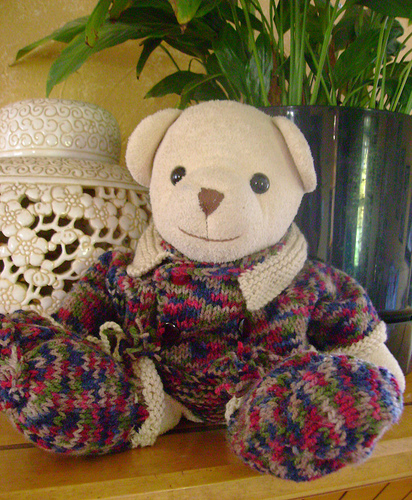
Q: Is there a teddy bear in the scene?
A: Yes, there is a teddy bear.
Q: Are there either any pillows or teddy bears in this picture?
A: Yes, there is a teddy bear.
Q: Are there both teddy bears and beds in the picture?
A: No, there is a teddy bear but no beds.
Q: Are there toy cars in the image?
A: No, there are no toy cars.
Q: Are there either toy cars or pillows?
A: No, there are no toy cars or pillows.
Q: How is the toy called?
A: The toy is a teddy bear.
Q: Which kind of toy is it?
A: The toy is a teddy bear.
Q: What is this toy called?
A: This is a teddy bear.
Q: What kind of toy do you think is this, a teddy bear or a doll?
A: This is a teddy bear.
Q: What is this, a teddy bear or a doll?
A: This is a teddy bear.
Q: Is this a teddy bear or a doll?
A: This is a teddy bear.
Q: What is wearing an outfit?
A: The teddy bear is wearing an outfit.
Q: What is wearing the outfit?
A: The teddy bear is wearing an outfit.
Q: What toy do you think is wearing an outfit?
A: The toy is a teddy bear.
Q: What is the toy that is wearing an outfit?
A: The toy is a teddy bear.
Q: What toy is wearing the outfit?
A: The toy is a teddy bear.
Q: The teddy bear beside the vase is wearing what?
A: The teddy bear is wearing an outfit.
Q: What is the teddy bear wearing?
A: The teddy bear is wearing an outfit.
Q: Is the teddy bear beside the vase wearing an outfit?
A: Yes, the teddy bear is wearing an outfit.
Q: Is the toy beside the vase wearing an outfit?
A: Yes, the teddy bear is wearing an outfit.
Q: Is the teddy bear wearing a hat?
A: No, the teddy bear is wearing an outfit.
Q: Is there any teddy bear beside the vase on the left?
A: Yes, there is a teddy bear beside the vase.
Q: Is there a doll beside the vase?
A: No, there is a teddy bear beside the vase.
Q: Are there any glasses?
A: No, there are no glasses.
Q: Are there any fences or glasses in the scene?
A: No, there are no glasses or fences.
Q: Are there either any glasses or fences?
A: No, there are no glasses or fences.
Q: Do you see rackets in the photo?
A: No, there are no rackets.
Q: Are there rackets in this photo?
A: No, there are no rackets.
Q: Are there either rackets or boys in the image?
A: No, there are no rackets or boys.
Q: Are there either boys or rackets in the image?
A: No, there are no rackets or boys.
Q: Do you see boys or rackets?
A: No, there are no rackets or boys.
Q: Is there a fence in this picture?
A: No, there are no fences.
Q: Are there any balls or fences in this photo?
A: No, there are no fences or balls.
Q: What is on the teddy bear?
A: The outfit is on the teddy bear.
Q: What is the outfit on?
A: The outfit is on the teddy bear.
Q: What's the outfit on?
A: The outfit is on the teddy bear.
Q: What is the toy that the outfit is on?
A: The toy is a teddy bear.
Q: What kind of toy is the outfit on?
A: The outfit is on the teddy bear.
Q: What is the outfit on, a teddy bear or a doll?
A: The outfit is on a teddy bear.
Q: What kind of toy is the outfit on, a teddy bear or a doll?
A: The outfit is on a teddy bear.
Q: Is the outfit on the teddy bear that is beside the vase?
A: Yes, the outfit is on the teddy bear.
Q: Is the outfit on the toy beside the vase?
A: Yes, the outfit is on the teddy bear.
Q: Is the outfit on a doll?
A: No, the outfit is on the teddy bear.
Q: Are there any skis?
A: No, there are no skis.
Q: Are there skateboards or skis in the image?
A: No, there are no skis or skateboards.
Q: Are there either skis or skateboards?
A: No, there are no skis or skateboards.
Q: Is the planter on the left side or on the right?
A: The planter is on the right of the image.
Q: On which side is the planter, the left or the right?
A: The planter is on the right of the image.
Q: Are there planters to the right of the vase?
A: Yes, there is a planter to the right of the vase.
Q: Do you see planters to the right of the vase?
A: Yes, there is a planter to the right of the vase.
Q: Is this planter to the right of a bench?
A: No, the planter is to the right of the vase.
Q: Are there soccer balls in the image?
A: No, there are no soccer balls.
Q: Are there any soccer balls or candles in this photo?
A: No, there are no soccer balls or candles.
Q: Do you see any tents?
A: No, there are no tents.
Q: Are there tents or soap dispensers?
A: No, there are no tents or soap dispensers.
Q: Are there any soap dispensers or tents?
A: No, there are no tents or soap dispensers.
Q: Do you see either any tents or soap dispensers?
A: No, there are no tents or soap dispensers.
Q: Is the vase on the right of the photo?
A: No, the vase is on the left of the image.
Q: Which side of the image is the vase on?
A: The vase is on the left of the image.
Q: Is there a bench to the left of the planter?
A: No, there is a vase to the left of the planter.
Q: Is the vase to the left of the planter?
A: Yes, the vase is to the left of the planter.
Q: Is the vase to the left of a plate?
A: No, the vase is to the left of the planter.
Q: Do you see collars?
A: Yes, there is a collar.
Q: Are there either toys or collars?
A: Yes, there is a collar.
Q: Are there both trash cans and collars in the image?
A: No, there is a collar but no trash cans.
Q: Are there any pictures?
A: No, there are no pictures.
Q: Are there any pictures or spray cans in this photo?
A: No, there are no pictures or spray cans.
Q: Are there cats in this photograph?
A: No, there are no cats.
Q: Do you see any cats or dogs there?
A: No, there are no cats or dogs.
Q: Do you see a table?
A: Yes, there is a table.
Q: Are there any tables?
A: Yes, there is a table.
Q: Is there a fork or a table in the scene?
A: Yes, there is a table.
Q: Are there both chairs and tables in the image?
A: No, there is a table but no chairs.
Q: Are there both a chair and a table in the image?
A: No, there is a table but no chairs.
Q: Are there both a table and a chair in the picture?
A: No, there is a table but no chairs.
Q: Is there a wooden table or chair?
A: Yes, there is a wood table.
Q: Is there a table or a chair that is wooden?
A: Yes, the table is wooden.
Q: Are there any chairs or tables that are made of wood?
A: Yes, the table is made of wood.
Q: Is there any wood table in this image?
A: Yes, there is a wood table.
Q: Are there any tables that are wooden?
A: Yes, there is a table that is wooden.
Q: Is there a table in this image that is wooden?
A: Yes, there is a table that is wooden.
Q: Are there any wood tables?
A: Yes, there is a table that is made of wood.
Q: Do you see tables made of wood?
A: Yes, there is a table that is made of wood.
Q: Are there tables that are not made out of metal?
A: Yes, there is a table that is made of wood.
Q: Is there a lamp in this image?
A: No, there are no lamps.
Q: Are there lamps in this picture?
A: No, there are no lamps.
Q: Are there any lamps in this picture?
A: No, there are no lamps.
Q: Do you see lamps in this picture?
A: No, there are no lamps.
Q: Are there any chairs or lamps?
A: No, there are no lamps or chairs.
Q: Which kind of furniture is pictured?
A: The furniture is a table.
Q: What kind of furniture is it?
A: The piece of furniture is a table.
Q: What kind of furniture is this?
A: This is a table.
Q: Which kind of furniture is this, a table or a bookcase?
A: This is a table.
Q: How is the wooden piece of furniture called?
A: The piece of furniture is a table.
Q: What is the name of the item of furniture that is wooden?
A: The piece of furniture is a table.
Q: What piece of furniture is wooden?
A: The piece of furniture is a table.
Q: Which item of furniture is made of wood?
A: The piece of furniture is a table.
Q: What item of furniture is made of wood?
A: The piece of furniture is a table.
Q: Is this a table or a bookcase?
A: This is a table.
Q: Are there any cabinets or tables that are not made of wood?
A: No, there is a table but it is made of wood.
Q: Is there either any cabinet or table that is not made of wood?
A: No, there is a table but it is made of wood.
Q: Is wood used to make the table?
A: Yes, the table is made of wood.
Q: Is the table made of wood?
A: Yes, the table is made of wood.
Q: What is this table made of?
A: The table is made of wood.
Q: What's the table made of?
A: The table is made of wood.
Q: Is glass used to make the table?
A: No, the table is made of wood.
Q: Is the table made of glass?
A: No, the table is made of wood.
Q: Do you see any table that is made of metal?
A: No, there is a table but it is made of wood.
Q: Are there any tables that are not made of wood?
A: No, there is a table but it is made of wood.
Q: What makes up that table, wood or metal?
A: The table is made of wood.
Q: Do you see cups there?
A: No, there are no cups.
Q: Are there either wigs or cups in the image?
A: No, there are no cups or wigs.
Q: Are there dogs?
A: No, there are no dogs.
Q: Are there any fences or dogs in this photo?
A: No, there are no dogs or fences.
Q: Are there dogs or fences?
A: No, there are no dogs or fences.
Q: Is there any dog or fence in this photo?
A: No, there are no dogs or fences.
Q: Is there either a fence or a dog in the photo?
A: No, there are no dogs or fences.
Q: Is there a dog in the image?
A: No, there are no dogs.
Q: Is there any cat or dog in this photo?
A: No, there are no dogs or cats.